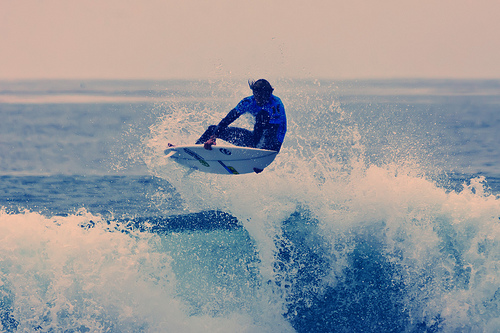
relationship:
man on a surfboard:
[195, 77, 290, 159] [159, 143, 277, 178]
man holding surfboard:
[167, 79, 286, 156] [188, 139, 271, 181]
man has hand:
[167, 79, 286, 156] [200, 137, 216, 149]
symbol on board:
[220, 148, 232, 155] [159, 145, 278, 176]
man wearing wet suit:
[167, 79, 286, 156] [207, 96, 284, 145]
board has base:
[159, 142, 279, 177] [166, 147, 274, 172]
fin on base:
[161, 146, 175, 160] [166, 147, 274, 172]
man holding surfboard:
[167, 79, 286, 156] [162, 140, 285, 178]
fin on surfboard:
[181, 143, 209, 171] [155, 138, 270, 192]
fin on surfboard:
[249, 154, 280, 178] [155, 138, 270, 192]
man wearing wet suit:
[167, 79, 286, 156] [193, 96, 288, 151]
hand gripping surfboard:
[201, 135, 233, 159] [151, 137, 278, 183]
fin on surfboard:
[164, 150, 177, 157] [159, 143, 277, 178]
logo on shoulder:
[272, 102, 284, 117] [269, 95, 285, 125]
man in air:
[167, 79, 286, 156] [0, 0, 499, 221]